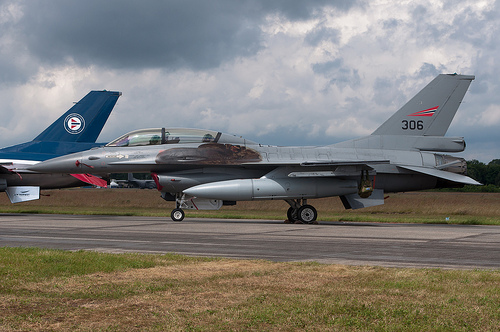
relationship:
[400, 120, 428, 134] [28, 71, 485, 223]
number on plane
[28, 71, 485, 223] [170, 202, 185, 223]
plane with wheel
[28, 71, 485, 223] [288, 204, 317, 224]
plane with wheel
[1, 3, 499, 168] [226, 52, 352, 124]
sky has cloud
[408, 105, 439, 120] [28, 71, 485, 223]
design on plane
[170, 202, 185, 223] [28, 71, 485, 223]
wheel on plane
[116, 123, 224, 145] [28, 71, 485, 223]
cockpit of plane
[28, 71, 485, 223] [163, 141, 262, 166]
plane has rust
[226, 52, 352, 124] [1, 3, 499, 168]
cloud in sky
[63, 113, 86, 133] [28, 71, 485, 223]
circle on plane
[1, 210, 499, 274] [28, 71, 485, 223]
runway under plane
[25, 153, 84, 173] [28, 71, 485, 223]
nose of plane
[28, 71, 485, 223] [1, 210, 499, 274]
plane on runway